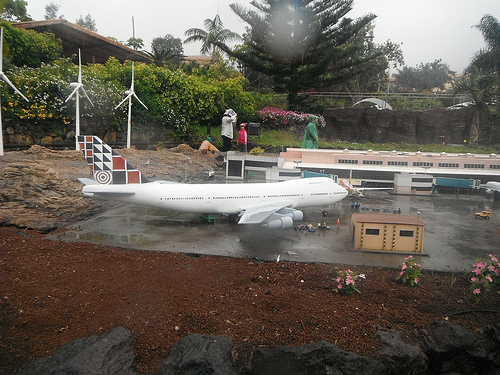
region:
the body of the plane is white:
[80, 177, 354, 212]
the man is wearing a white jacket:
[218, 113, 238, 142]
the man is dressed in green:
[302, 113, 322, 148]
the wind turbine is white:
[117, 62, 146, 149]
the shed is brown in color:
[350, 211, 429, 261]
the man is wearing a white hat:
[223, 107, 233, 117]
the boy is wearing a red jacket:
[236, 127, 248, 147]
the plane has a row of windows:
[153, 193, 340, 203]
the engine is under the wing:
[255, 210, 295, 232]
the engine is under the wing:
[275, 206, 302, 220]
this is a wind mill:
[63, 20, 93, 157]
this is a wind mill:
[115, 47, 152, 144]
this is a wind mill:
[0, 25, 28, 157]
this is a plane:
[69, 130, 351, 228]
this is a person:
[212, 100, 239, 150]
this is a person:
[236, 118, 256, 153]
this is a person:
[296, 106, 321, 151]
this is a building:
[288, 138, 498, 190]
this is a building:
[342, 210, 431, 259]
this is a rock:
[33, 315, 136, 372]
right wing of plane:
[231, 191, 299, 245]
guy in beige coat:
[211, 100, 255, 147]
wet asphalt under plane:
[81, 203, 171, 263]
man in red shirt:
[232, 116, 252, 147]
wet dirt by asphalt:
[92, 258, 282, 350]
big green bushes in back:
[51, 42, 296, 132]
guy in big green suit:
[288, 105, 339, 150]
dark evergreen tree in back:
[225, 25, 355, 120]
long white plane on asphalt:
[81, 148, 397, 229]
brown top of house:
[12, 10, 179, 56]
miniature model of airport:
[145, 144, 487, 249]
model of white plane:
[92, 172, 354, 233]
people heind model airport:
[195, 100, 253, 170]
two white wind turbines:
[60, 47, 151, 152]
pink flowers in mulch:
[324, 253, 426, 303]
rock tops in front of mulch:
[170, 322, 387, 367]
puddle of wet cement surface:
[73, 214, 172, 252]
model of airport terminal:
[355, 143, 453, 194]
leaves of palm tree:
[190, 20, 236, 61]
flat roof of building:
[56, 19, 141, 63]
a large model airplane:
[62, 128, 350, 231]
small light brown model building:
[338, 210, 427, 260]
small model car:
[470, 200, 497, 226]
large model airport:
[220, 140, 496, 205]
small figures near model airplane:
[255, 175, 350, 245]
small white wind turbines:
[0, 40, 150, 155]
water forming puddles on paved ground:
[50, 195, 170, 255]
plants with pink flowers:
[320, 246, 498, 311]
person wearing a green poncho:
[297, 107, 327, 157]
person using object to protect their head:
[218, 103, 246, 150]